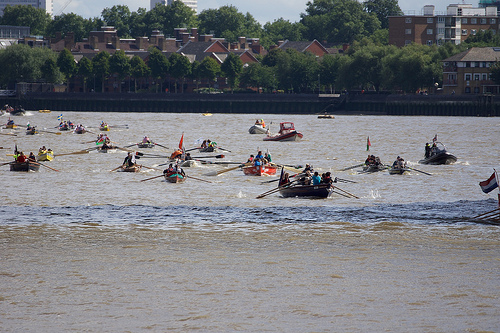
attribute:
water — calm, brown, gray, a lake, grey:
[0, 110, 498, 333]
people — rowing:
[283, 164, 332, 186]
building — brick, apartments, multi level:
[385, 0, 499, 48]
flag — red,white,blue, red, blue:
[479, 166, 499, 194]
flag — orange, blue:
[176, 132, 185, 152]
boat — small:
[167, 150, 191, 163]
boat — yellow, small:
[37, 145, 53, 160]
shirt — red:
[17, 155, 25, 161]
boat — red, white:
[264, 122, 297, 142]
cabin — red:
[279, 121, 294, 133]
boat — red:
[239, 164, 277, 175]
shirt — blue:
[312, 176, 321, 183]